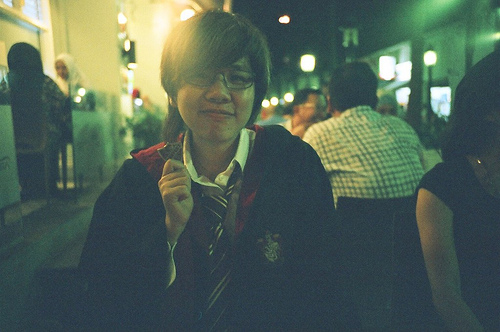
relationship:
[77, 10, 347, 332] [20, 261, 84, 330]
man sitting in chair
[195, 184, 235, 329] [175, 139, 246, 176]
tie on shirt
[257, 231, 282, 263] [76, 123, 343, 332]
emblem on top of cloak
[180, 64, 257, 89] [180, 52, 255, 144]
eye glasses on face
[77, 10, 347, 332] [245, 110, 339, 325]
man wearing cloak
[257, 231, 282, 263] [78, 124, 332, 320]
emblem on cloak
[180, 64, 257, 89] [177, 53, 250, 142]
eye glasses on face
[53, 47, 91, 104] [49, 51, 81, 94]
woman wearing scarf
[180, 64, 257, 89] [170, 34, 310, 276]
eye glasses of person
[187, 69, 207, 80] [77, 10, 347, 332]
brown eye of man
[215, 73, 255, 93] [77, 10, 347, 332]
eye of man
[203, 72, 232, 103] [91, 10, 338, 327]
small nose of person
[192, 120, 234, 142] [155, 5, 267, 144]
chin of face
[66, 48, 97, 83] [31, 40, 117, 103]
scarf on woman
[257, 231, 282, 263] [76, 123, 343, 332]
emblem on cloak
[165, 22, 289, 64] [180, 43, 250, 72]
hair with bangs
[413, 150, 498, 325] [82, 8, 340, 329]
shirt for woman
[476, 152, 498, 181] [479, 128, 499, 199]
necklace on neck